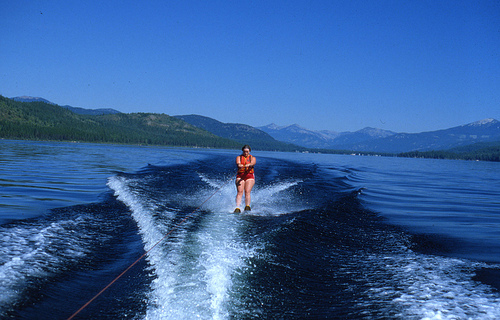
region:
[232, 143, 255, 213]
A chubby young woman water skiing.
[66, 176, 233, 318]
The wire holding a woman who's water skiing.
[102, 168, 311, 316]
The shimmering watermark in the ocean.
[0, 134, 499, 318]
The deep blue sea under the sky.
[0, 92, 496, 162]
All different types of hills.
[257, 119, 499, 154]
Several blue mountains further in the horizon.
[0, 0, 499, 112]
The big blue sky in a lovely day.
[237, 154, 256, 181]
The red outfit the woman is wearing.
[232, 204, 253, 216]
The water skis used to practice the sport.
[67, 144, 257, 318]
The woman is being dragged.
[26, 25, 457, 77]
The sky is clear.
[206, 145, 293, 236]
She is on the water.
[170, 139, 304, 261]
She is jet sking.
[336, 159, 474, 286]
The water is calm.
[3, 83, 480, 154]
The mountains are in the back.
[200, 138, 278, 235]
She is wearing red.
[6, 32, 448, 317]
The lake is large.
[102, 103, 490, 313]
The woman is the only one on the water.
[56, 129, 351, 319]
She is holding a rope.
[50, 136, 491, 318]
The water is moving.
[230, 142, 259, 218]
woman waterskiing on the lake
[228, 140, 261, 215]
woman waterskiing in a red swim suit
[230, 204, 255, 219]
the waterskiies that the woman is using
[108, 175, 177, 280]
rippling white waves made from the boat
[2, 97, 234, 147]
green mountains surround the lake shore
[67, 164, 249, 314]
the rope that connects the waterskiier and the boat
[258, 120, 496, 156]
snowcapped mountain range in the background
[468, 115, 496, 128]
snowcapped mountain peak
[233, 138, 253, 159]
the woman is wearing sunglasses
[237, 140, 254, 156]
the womans hair is brown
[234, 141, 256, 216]
A woman on skies in the water.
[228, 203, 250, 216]
Skies on a woman in the water.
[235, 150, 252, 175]
Orange safety vest on a woman water skiing.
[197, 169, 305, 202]
White waves behind a water skier.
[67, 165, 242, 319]
A line going to a woman.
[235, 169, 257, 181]
Red shorts on a woman.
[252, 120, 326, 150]
Two peaks to the back right of a woman.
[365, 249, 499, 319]
Small white waves on the bottom right.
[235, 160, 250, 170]
Hands of a woman water skier.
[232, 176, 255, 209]
Legs on a woman who is water skiing.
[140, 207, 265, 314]
the wake in the water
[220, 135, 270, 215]
a water skier holding on to a rope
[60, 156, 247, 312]
a rope pulling a water skier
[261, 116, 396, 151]
mountains in the distance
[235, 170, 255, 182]
a red swimsuit on a water skier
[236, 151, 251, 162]
an orange life vest on a water skier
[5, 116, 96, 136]
a tree covered hillside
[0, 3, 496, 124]
a beautiful blue sky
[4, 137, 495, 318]
deep dark blue water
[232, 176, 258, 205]
the legs of a water skier